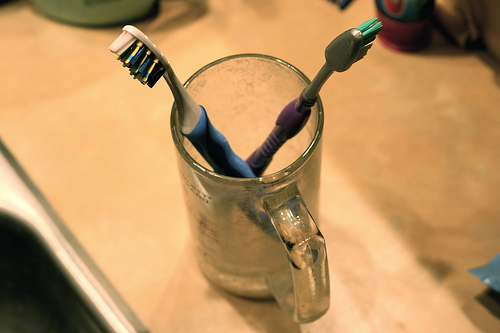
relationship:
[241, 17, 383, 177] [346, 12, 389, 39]
tooth brush with bristles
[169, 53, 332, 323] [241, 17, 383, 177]
cup with tooth brush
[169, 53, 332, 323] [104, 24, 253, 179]
cup with toothbrush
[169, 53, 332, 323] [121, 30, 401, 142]
cup with toothbrushes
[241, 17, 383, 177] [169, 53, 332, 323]
tooth brush in cup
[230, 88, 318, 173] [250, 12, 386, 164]
handle of toothbrush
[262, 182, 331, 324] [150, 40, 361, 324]
handle of mug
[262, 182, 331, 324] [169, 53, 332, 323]
handle on cup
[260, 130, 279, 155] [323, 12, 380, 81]
purple stripe on toothbrush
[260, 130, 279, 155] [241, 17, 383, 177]
purple stripe on tooth brush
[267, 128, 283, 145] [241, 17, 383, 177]
purple stripe on tooth brush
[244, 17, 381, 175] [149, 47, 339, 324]
tooth brush in cup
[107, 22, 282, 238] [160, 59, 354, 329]
blue toothbrush in glass cup